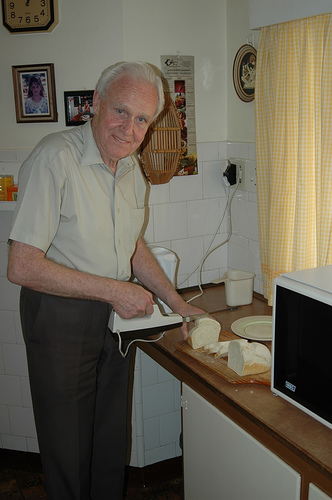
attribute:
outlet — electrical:
[220, 144, 248, 193]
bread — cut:
[221, 334, 283, 384]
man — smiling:
[13, 29, 200, 346]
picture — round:
[8, 58, 65, 129]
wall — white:
[98, 11, 180, 44]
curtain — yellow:
[256, 30, 327, 122]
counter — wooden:
[149, 273, 323, 419]